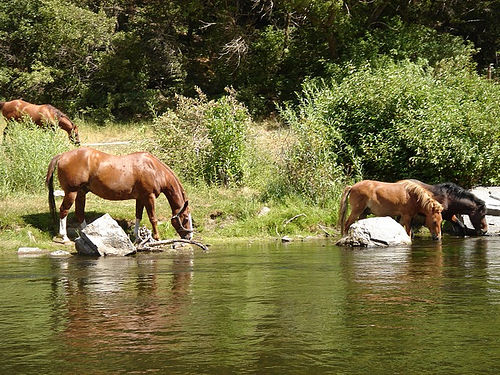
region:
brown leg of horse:
[56, 187, 76, 237]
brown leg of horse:
[74, 193, 86, 229]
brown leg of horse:
[132, 203, 147, 238]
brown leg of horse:
[146, 195, 162, 237]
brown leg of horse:
[344, 204, 357, 228]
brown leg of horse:
[398, 213, 412, 231]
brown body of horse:
[61, 149, 167, 207]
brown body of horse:
[348, 175, 415, 218]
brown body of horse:
[4, 98, 59, 129]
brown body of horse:
[403, 176, 443, 207]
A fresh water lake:
[3, 233, 498, 372]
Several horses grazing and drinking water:
[0, 99, 485, 239]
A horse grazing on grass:
[0, 99, 81, 145]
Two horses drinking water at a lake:
[338, 179, 490, 238]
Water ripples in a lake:
[44, 293, 169, 328]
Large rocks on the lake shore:
[16, 187, 498, 258]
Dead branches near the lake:
[136, 213, 337, 253]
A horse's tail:
[46, 156, 61, 231]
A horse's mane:
[443, 180, 486, 207]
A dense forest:
[4, 2, 498, 125]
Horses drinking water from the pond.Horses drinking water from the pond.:
[298, 162, 443, 260]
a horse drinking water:
[20, 116, 210, 285]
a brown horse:
[37, 138, 213, 253]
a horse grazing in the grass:
[4, 79, 89, 161]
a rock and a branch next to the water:
[58, 207, 231, 289]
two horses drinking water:
[323, 160, 492, 270]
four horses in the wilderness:
[0, 65, 493, 290]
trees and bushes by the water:
[18, 7, 498, 332]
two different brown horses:
[331, 183, 490, 242]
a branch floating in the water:
[125, 217, 230, 276]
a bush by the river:
[148, 80, 280, 267]